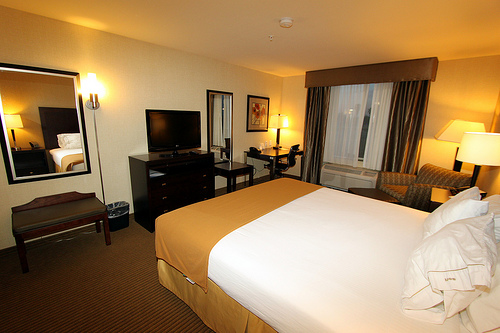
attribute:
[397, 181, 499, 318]
pillows — white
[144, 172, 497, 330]
bed — Yellow and white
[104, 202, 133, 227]
trash can — black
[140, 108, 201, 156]
tv — flat screen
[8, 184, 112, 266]
bench seat — cushioned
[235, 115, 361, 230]
desk — Black 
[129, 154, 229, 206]
dresser — Black 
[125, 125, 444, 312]
bed — made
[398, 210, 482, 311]
pillow — Large , white 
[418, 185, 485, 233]
pillow — Large , white 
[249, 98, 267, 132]
print — framed